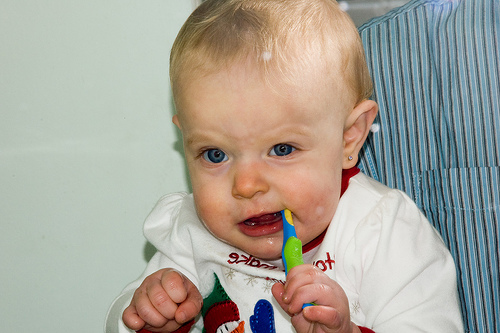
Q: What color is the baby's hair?
A: Blonde.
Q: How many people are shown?
A: Two.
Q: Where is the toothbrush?
A: In the baby's mouth.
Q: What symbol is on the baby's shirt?
A: A snowman.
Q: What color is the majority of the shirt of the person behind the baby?
A: Blue.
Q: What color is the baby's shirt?
A: White.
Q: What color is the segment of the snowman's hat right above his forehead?
A: Red.